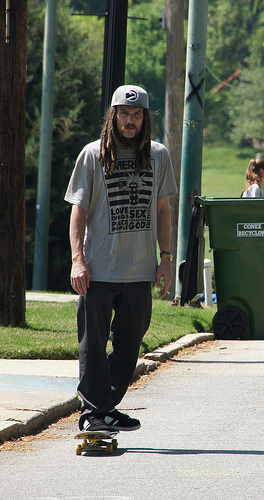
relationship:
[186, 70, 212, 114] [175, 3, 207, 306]
black x on a pole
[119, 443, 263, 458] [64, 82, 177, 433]
shadow of skateboarder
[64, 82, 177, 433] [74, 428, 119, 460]
skateboarder on a skateboard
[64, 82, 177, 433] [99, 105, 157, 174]
skateboarder with dreadlocks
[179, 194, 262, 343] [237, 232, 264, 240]
trash can says recycle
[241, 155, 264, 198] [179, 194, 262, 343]
woman beyond trash can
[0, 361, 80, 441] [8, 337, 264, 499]
sidewalk by street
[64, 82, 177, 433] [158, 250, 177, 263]
skateboarder wears a wristwatch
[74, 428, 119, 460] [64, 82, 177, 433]
skateboard of skateboarder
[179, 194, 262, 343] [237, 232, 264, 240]
trash can used to recycle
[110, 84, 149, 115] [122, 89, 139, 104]
cap has a logo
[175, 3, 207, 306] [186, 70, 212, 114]
pole has a black x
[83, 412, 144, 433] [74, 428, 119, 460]
shoes on skateboard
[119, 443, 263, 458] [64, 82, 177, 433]
shadow cast by skateboarder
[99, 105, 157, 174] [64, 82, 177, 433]
dreadlocks of skateboarder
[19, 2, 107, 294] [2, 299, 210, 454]
tree to front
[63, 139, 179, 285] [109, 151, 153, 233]
shirt has black print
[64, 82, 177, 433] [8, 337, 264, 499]
skateboarder on street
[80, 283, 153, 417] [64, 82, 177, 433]
pants on skateboarder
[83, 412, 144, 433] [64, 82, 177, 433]
shoes of skateboarder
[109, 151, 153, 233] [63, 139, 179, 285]
black print on a shirt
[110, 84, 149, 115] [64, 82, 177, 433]
cap on a skateboarder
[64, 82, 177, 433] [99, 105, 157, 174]
skateboarder wearing dreadlocks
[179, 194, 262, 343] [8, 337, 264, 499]
trash can on street